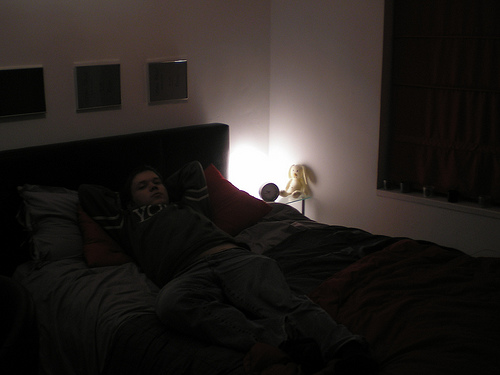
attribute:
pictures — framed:
[1, 57, 189, 127]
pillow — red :
[167, 164, 287, 239]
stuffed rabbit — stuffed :
[275, 162, 312, 199]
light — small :
[253, 160, 313, 202]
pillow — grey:
[22, 181, 96, 268]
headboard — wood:
[1, 121, 228, 181]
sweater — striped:
[74, 157, 254, 291]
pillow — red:
[184, 160, 267, 229]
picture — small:
[143, 57, 192, 107]